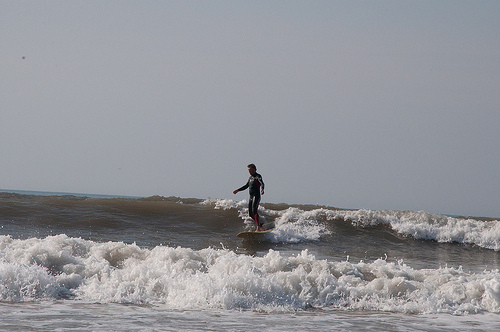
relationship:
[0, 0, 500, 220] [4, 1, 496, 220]
cloud in sky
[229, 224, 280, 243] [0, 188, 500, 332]
surfboard on water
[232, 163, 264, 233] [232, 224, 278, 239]
man on surfboard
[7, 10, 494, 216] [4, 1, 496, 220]
cloud in sky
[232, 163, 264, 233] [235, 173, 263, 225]
man wearing wetsuit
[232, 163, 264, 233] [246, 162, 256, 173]
man with black hair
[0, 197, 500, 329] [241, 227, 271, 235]
wave pushing surfboard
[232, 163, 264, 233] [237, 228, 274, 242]
man on surfboard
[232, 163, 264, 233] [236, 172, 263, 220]
man wearing wetsuit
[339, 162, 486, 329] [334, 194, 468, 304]
water from a wave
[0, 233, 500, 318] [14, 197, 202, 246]
wave in ocean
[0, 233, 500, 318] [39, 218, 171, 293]
wave in ocean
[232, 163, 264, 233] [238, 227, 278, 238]
man on surfboard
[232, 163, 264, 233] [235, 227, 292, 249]
man on surfboard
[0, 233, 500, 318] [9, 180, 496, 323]
wave crashing against ocean